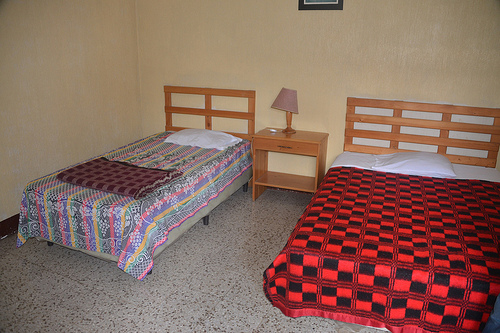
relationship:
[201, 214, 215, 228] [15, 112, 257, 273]
feet in bed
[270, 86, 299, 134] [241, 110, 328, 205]
lamp in nightstand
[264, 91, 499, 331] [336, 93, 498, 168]
bed in headboard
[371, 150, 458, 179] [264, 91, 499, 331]
pillow in bed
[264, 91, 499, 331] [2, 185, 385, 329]
bed on floor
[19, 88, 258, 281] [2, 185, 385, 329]
bed on floor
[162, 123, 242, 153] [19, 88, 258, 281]
pillow on bed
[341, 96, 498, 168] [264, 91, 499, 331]
headboard on bed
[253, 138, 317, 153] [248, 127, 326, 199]
drawer on night stand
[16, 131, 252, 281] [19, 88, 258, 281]
bedspread on bed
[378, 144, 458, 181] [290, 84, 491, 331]
pillow on bed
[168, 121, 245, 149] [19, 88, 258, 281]
pillow on bed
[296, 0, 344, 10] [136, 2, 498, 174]
picture on wall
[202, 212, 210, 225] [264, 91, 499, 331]
leg on bed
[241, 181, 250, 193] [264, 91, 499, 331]
leg on bed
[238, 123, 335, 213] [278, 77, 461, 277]
stand to right bed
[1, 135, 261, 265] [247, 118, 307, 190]
bed next to night stand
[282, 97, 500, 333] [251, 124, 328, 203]
bed next to night stand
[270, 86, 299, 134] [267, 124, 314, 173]
lamp on table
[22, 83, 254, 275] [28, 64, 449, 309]
bed in room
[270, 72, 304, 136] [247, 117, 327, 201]
lamp on end table